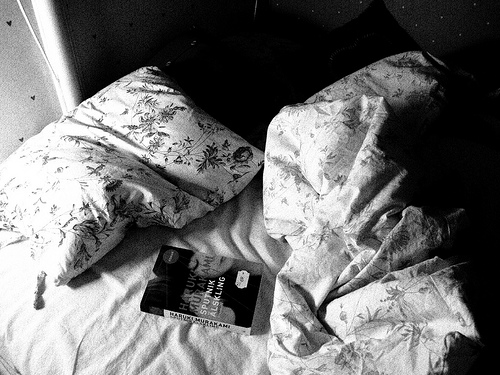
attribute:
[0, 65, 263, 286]
pillow cover —  pillow's 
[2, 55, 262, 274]
pillowcase — floral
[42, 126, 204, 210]
pillow — w/ cover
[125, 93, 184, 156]
design —  floral 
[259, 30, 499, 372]
sheet — top, flat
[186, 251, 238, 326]
edge — book's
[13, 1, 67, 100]
string — white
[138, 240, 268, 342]
book —  paperback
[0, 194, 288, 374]
sheet — white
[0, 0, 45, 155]
blind —  window's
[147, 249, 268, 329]
image —  book's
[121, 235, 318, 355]
book —  closed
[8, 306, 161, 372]
sheet — solid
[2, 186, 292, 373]
fitted sheet — wrinkled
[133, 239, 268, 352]
book — swedish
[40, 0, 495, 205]
window — w/ sill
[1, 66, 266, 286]
pillow case — match 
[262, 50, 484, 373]
comforter — match 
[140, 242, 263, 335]
novel —  romance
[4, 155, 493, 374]
bed — not made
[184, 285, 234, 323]
man — young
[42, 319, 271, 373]
sheet —  bed's